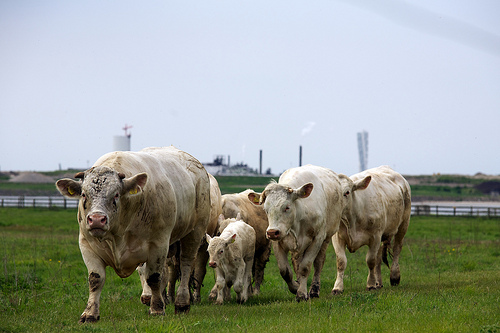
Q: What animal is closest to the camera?
A: The first cow in line.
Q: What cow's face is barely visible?
A: The cow behind the third cow.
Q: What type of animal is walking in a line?
A: A herd of cows.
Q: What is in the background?
A: A building.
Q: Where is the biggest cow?
A: In front.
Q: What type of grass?
A: Green patch.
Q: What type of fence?
A: Long and wooden.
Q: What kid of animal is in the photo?
A: Cows.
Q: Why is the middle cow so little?
A: He is a baby.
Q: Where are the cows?
A: On a field of grass.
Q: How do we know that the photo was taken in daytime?
A: It's light outside.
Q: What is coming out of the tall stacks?
A: Smoke.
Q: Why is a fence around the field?
A: To keep the cows inside.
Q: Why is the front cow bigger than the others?
A: It is a bull.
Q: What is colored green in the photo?
A: Grass.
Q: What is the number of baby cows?
A: One.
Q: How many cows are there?
A: Six.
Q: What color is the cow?
A: White.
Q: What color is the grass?
A: Green.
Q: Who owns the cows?
A: The farmer.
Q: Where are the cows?
A: In the field.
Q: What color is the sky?
A: Grey.